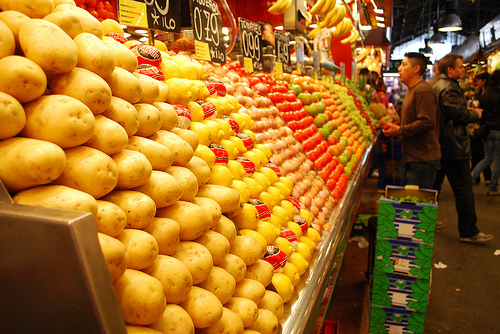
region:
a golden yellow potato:
[26, 91, 95, 149]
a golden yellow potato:
[2, 133, 62, 186]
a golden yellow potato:
[62, 144, 118, 198]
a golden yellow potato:
[3, 57, 48, 103]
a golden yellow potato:
[19, 18, 76, 75]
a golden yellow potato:
[49, 62, 109, 113]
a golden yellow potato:
[74, 32, 114, 74]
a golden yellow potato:
[109, 68, 144, 103]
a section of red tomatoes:
[252, 72, 352, 205]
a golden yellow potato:
[107, 268, 167, 326]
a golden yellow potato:
[260, 287, 287, 319]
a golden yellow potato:
[252, 304, 279, 331]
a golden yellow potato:
[222, 294, 259, 326]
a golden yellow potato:
[233, 276, 265, 303]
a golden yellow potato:
[247, 255, 274, 287]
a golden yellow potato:
[229, 235, 265, 264]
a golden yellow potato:
[222, 253, 246, 278]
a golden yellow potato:
[202, 263, 234, 303]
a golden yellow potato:
[187, 157, 214, 185]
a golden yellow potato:
[198, 184, 240, 212]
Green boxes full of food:
[383, 200, 430, 237]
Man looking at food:
[396, 54, 436, 161]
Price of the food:
[193, 7, 220, 39]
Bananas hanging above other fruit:
[328, 8, 352, 34]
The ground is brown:
[466, 261, 497, 301]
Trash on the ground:
[435, 256, 466, 307]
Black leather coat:
[441, 81, 462, 136]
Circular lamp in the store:
[439, 15, 461, 30]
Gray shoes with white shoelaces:
[462, 231, 494, 240]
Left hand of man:
[385, 121, 399, 133]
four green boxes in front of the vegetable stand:
[368, 182, 436, 332]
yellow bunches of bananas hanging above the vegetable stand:
[268, 0, 358, 43]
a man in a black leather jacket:
[434, 52, 493, 243]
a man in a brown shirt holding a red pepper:
[381, 50, 443, 188]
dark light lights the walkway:
[436, 11, 463, 31]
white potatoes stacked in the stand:
[1, 1, 279, 332]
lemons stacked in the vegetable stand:
[103, 17, 320, 299]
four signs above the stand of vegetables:
[121, 0, 291, 74]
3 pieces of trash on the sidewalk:
[433, 247, 498, 291]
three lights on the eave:
[373, 6, 385, 28]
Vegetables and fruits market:
[0, 10, 485, 258]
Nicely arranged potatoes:
[8, 17, 168, 320]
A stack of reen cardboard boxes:
[356, 185, 453, 332]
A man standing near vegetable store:
[80, 38, 438, 210]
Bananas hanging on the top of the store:
[241, 0, 378, 50]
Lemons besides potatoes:
[104, 37, 260, 270]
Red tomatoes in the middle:
[245, 58, 359, 198]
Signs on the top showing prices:
[131, 1, 299, 60]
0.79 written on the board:
[173, 6, 240, 48]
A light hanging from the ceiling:
[431, 5, 470, 40]